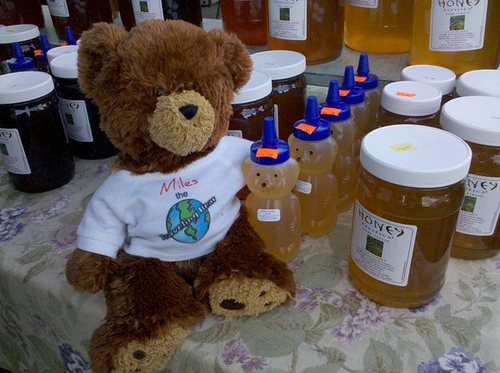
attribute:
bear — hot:
[65, 20, 296, 372]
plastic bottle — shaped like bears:
[240, 112, 303, 264]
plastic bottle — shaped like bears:
[285, 94, 339, 239]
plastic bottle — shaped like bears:
[318, 76, 358, 213]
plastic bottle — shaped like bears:
[337, 60, 371, 186]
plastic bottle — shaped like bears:
[352, 50, 380, 135]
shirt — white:
[62, 132, 275, 264]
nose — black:
[173, 102, 200, 117]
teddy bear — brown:
[65, 13, 295, 369]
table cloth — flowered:
[314, 292, 480, 360]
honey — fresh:
[2, 70, 78, 198]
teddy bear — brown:
[52, 7, 306, 372]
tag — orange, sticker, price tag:
[252, 144, 284, 164]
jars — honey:
[377, 44, 495, 306]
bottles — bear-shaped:
[261, 67, 387, 270]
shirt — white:
[71, 136, 262, 263]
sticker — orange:
[386, 140, 420, 158]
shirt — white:
[134, 164, 302, 299]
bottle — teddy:
[249, 104, 304, 267]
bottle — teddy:
[281, 94, 336, 237]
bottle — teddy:
[318, 77, 353, 211]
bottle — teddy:
[339, 67, 368, 144]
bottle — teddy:
[354, 56, 383, 126]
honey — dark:
[0, 35, 110, 193]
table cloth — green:
[2, 40, 484, 369]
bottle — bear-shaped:
[242, 112, 302, 263]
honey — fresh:
[349, 166, 465, 307]